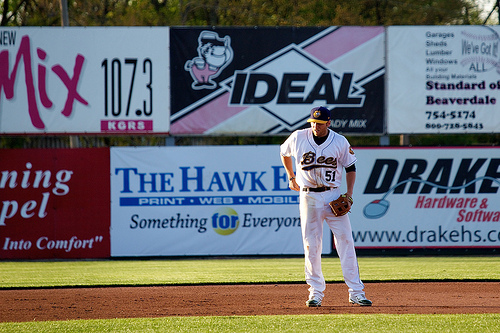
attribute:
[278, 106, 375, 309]
player — looking, playing baseball, standing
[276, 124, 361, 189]
jersey — for baseball, team's, short sleeve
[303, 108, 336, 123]
cap — dark, yellow, team's, black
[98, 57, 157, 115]
numbers — black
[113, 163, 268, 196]
hawk — blue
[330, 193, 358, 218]
glove — light, in hand, on left hand, yellow, brown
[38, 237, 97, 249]
comfort — white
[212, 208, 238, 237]
circle — yellow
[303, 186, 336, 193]
belt — dark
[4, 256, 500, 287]
grass — green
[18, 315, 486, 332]
grass — green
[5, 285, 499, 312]
dirt — red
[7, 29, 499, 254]
advertising — on background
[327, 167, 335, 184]
51 — dakr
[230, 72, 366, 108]
ideal — dark, large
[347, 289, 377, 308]
shoes — white, black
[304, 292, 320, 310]
shoes — white, black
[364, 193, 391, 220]
mouse — drawing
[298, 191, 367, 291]
pants — white